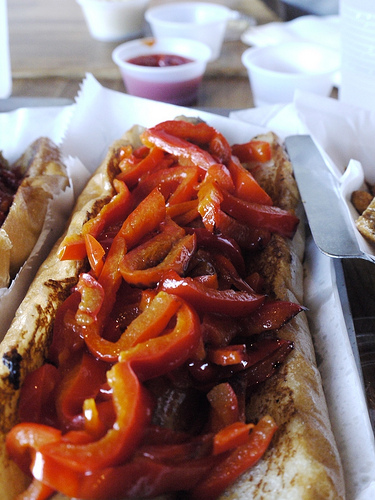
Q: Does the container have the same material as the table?
A: No, the container is made of plastic and the table is made of wood.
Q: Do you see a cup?
A: Yes, there is a cup.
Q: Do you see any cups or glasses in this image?
A: Yes, there is a cup.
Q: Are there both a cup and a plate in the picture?
A: No, there is a cup but no plates.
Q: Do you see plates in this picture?
A: No, there are no plates.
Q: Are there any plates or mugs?
A: No, there are no plates or mugs.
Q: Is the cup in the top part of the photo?
A: Yes, the cup is in the top of the image.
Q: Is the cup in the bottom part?
A: No, the cup is in the top of the image.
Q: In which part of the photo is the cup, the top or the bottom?
A: The cup is in the top of the image.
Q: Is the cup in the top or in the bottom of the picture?
A: The cup is in the top of the image.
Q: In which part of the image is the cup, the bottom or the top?
A: The cup is in the top of the image.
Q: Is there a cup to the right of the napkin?
A: No, the cup is to the left of the napkin.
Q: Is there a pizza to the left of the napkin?
A: No, there is a cup to the left of the napkin.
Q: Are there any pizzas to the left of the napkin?
A: No, there is a cup to the left of the napkin.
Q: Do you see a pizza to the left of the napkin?
A: No, there is a cup to the left of the napkin.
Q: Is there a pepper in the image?
A: Yes, there is a pepper.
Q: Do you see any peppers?
A: Yes, there is a pepper.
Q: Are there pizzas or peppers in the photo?
A: Yes, there is a pepper.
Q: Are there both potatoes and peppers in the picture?
A: No, there is a pepper but no potatoes.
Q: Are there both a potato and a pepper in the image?
A: No, there is a pepper but no potatoes.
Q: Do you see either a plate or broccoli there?
A: No, there are no plates or broccoli.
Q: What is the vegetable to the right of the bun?
A: The vegetable is a pepper.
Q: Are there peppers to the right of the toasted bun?
A: Yes, there is a pepper to the right of the bun.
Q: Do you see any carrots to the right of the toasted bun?
A: No, there is a pepper to the right of the bun.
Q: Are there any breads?
A: Yes, there is a bread.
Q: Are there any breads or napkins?
A: Yes, there is a bread.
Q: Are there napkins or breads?
A: Yes, there is a bread.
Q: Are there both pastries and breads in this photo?
A: No, there is a bread but no pastries.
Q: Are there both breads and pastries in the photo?
A: No, there is a bread but no pastries.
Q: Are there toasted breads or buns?
A: Yes, there is a toasted bread.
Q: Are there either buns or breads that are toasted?
A: Yes, the bread is toasted.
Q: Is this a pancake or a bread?
A: This is a bread.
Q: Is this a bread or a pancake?
A: This is a bread.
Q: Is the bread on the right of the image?
A: Yes, the bread is on the right of the image.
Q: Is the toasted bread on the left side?
A: No, the bread is on the right of the image.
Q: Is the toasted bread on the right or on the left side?
A: The bread is on the right of the image.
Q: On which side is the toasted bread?
A: The bread is on the right of the image.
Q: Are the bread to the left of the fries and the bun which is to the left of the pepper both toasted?
A: Yes, both the bread and the bun are toasted.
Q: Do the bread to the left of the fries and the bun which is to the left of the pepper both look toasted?
A: Yes, both the bread and the bun are toasted.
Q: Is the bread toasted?
A: Yes, the bread is toasted.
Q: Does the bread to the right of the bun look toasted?
A: Yes, the bread is toasted.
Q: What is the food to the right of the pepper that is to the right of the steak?
A: The food is a bread.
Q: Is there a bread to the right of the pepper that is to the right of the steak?
A: Yes, there is a bread to the right of the pepper.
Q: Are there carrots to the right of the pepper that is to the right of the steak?
A: No, there is a bread to the right of the pepper.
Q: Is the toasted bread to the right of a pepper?
A: Yes, the bread is to the right of a pepper.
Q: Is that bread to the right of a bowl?
A: No, the bread is to the right of a pepper.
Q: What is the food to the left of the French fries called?
A: The food is a bread.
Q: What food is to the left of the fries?
A: The food is a bread.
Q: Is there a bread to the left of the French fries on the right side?
A: Yes, there is a bread to the left of the fries.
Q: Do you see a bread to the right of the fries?
A: No, the bread is to the left of the fries.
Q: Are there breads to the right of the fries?
A: No, the bread is to the left of the fries.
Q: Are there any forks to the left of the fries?
A: No, there is a bread to the left of the fries.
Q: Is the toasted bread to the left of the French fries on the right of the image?
A: Yes, the bread is to the left of the fries.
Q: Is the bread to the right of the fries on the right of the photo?
A: No, the bread is to the left of the French fries.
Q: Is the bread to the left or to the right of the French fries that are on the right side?
A: The bread is to the left of the French fries.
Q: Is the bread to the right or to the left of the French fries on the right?
A: The bread is to the left of the French fries.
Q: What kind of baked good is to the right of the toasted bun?
A: The food is a bread.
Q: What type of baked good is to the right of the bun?
A: The food is a bread.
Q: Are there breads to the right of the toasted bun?
A: Yes, there is a bread to the right of the bun.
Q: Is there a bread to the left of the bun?
A: No, the bread is to the right of the bun.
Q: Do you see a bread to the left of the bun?
A: No, the bread is to the right of the bun.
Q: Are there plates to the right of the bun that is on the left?
A: No, there is a bread to the right of the bun.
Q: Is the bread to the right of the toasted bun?
A: Yes, the bread is to the right of the bun.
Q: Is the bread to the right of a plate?
A: No, the bread is to the right of the bun.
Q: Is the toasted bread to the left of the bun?
A: No, the bread is to the right of the bun.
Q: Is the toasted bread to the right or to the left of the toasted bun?
A: The bread is to the right of the bun.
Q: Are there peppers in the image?
A: Yes, there is a pepper.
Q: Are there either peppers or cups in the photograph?
A: Yes, there is a pepper.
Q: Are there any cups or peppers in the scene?
A: Yes, there is a pepper.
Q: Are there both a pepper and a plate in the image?
A: No, there is a pepper but no plates.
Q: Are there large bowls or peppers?
A: Yes, there is a large pepper.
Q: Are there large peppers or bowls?
A: Yes, there is a large pepper.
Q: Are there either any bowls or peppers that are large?
A: Yes, the pepper is large.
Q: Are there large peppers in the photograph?
A: Yes, there is a large pepper.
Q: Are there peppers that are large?
A: Yes, there is a pepper that is large.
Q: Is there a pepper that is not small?
A: Yes, there is a large pepper.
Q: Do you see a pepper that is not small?
A: Yes, there is a large pepper.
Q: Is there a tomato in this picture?
A: No, there are no tomatoes.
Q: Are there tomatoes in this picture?
A: No, there are no tomatoes.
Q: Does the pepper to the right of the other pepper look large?
A: Yes, the pepper is large.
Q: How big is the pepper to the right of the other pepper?
A: The pepper is large.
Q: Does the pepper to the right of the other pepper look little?
A: No, the pepper is large.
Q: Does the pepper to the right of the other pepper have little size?
A: No, the pepper is large.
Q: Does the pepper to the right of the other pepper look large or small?
A: The pepper is large.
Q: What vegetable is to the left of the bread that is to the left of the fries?
A: The vegetable is a pepper.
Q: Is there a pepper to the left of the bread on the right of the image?
A: Yes, there is a pepper to the left of the bread.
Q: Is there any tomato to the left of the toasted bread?
A: No, there is a pepper to the left of the bread.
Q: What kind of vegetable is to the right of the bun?
A: The vegetable is a pepper.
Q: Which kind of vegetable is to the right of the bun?
A: The vegetable is a pepper.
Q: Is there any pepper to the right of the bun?
A: Yes, there is a pepper to the right of the bun.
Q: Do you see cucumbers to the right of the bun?
A: No, there is a pepper to the right of the bun.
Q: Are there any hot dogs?
A: Yes, there is a hot dog.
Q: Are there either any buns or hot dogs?
A: Yes, there is a hot dog.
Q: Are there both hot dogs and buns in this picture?
A: Yes, there are both a hot dog and a bun.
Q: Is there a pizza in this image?
A: No, there are no pizzas.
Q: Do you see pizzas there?
A: No, there are no pizzas.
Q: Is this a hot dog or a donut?
A: This is a hot dog.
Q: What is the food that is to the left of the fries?
A: The food is a hot dog.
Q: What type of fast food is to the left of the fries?
A: The food is a hot dog.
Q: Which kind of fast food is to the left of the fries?
A: The food is a hot dog.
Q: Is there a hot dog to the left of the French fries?
A: Yes, there is a hot dog to the left of the French fries.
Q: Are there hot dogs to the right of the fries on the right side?
A: No, the hot dog is to the left of the fries.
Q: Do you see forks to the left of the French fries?
A: No, there is a hot dog to the left of the French fries.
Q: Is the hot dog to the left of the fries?
A: Yes, the hot dog is to the left of the fries.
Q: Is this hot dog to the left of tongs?
A: No, the hot dog is to the left of the fries.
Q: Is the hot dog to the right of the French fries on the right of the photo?
A: No, the hot dog is to the left of the French fries.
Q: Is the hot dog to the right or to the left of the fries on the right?
A: The hot dog is to the left of the fries.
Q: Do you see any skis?
A: No, there are no skis.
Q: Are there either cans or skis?
A: No, there are no skis or cans.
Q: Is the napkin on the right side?
A: Yes, the napkin is on the right of the image.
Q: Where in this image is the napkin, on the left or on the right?
A: The napkin is on the right of the image.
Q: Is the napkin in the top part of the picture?
A: Yes, the napkin is in the top of the image.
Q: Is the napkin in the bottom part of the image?
A: No, the napkin is in the top of the image.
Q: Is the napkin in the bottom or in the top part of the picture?
A: The napkin is in the top of the image.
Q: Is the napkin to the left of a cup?
A: No, the napkin is to the right of a cup.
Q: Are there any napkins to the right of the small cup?
A: Yes, there is a napkin to the right of the cup.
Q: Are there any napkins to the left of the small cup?
A: No, the napkin is to the right of the cup.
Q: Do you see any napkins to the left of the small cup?
A: No, the napkin is to the right of the cup.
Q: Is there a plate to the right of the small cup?
A: No, there is a napkin to the right of the cup.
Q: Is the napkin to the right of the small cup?
A: Yes, the napkin is to the right of the cup.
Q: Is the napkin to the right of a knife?
A: No, the napkin is to the right of the cup.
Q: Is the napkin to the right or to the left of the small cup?
A: The napkin is to the right of the cup.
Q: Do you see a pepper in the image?
A: Yes, there is a pepper.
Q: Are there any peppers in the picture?
A: Yes, there is a pepper.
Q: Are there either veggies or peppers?
A: Yes, there is a pepper.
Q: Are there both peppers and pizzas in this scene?
A: No, there is a pepper but no pizzas.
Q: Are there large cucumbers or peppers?
A: Yes, there is a large pepper.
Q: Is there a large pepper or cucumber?
A: Yes, there is a large pepper.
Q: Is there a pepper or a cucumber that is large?
A: Yes, the pepper is large.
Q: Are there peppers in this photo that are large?
A: Yes, there is a pepper that is large.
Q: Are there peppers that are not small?
A: Yes, there is a large pepper.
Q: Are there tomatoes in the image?
A: No, there are no tomatoes.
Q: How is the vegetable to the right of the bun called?
A: The vegetable is a pepper.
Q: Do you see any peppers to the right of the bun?
A: Yes, there is a pepper to the right of the bun.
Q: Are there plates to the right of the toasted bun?
A: No, there is a pepper to the right of the bun.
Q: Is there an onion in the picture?
A: Yes, there is an onion.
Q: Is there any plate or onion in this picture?
A: Yes, there is an onion.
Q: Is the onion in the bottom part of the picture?
A: Yes, the onion is in the bottom of the image.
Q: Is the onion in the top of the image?
A: No, the onion is in the bottom of the image.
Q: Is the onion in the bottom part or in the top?
A: The onion is in the bottom of the image.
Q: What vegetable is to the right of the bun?
A: The vegetable is an onion.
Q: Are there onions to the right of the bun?
A: Yes, there is an onion to the right of the bun.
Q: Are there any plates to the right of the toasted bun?
A: No, there is an onion to the right of the bun.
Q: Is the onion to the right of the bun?
A: Yes, the onion is to the right of the bun.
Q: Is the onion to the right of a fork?
A: No, the onion is to the right of the bun.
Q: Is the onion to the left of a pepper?
A: No, the onion is to the right of a pepper.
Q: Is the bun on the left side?
A: Yes, the bun is on the left of the image.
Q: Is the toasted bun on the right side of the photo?
A: No, the bun is on the left of the image.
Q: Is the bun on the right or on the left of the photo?
A: The bun is on the left of the image.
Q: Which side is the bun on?
A: The bun is on the left of the image.